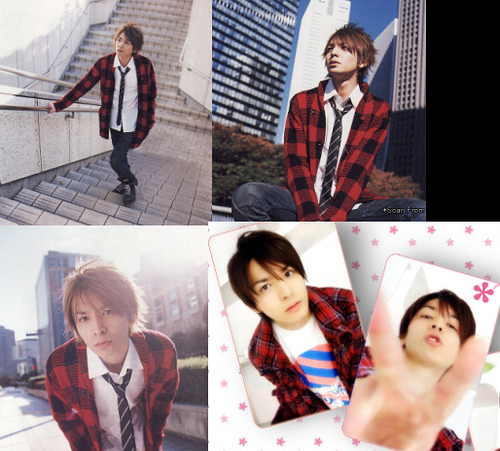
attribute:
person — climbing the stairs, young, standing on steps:
[47, 23, 162, 206]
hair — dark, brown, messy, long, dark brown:
[113, 23, 145, 55]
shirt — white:
[83, 348, 149, 451]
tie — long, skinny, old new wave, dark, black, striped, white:
[116, 64, 130, 128]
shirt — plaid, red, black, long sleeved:
[284, 76, 395, 222]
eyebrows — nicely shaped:
[67, 301, 120, 319]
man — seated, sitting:
[225, 22, 433, 220]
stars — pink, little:
[346, 227, 500, 304]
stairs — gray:
[3, 147, 212, 222]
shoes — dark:
[114, 178, 142, 205]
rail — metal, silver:
[1, 67, 106, 118]